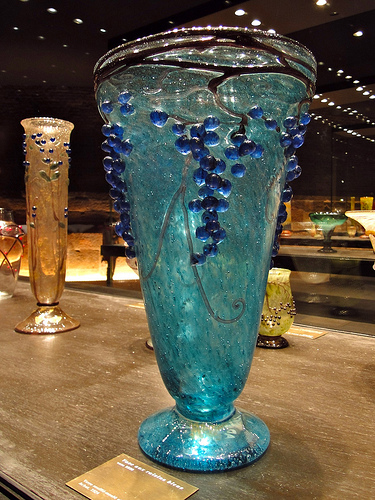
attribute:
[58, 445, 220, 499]
card — brown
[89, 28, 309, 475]
glass — blue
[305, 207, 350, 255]
glass — green, large 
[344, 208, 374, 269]
martini glass — large , white 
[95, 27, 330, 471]
glass — blue, large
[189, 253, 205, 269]
dot — blue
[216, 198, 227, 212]
dot — blue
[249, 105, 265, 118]
dot — blue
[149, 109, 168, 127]
dot — blue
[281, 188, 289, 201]
dot — blue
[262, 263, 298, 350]
glass — small, yellow 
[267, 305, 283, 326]
beads — brown 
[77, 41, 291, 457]
vase — tall, tan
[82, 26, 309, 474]
vase — metal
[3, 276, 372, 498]
table — large, wooden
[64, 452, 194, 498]
place card — golden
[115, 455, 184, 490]
lettering — white